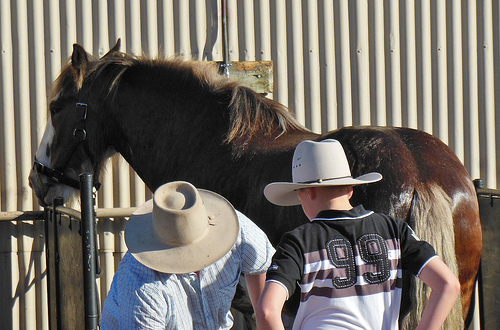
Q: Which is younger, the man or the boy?
A: The boy is younger than the man.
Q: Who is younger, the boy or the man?
A: The boy is younger than the man.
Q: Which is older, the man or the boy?
A: The man is older than the boy.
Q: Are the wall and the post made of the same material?
A: Yes, both the wall and the post are made of metal.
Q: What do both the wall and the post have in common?
A: The material, both the wall and the post are metallic.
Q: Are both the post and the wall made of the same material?
A: Yes, both the post and the wall are made of metal.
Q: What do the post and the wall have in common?
A: The material, both the post and the wall are metallic.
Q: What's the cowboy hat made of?
A: The cowboy hat is made of leather.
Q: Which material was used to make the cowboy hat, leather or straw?
A: The cowboy hat is made of leather.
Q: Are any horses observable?
A: Yes, there is a horse.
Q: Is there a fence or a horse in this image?
A: Yes, there is a horse.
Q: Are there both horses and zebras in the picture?
A: No, there is a horse but no zebras.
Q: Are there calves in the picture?
A: No, there are no calves.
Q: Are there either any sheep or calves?
A: No, there are no calves or sheep.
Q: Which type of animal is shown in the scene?
A: The animal is a horse.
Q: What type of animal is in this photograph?
A: The animal is a horse.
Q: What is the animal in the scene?
A: The animal is a horse.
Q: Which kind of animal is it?
A: The animal is a horse.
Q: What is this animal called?
A: This is a horse.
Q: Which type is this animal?
A: This is a horse.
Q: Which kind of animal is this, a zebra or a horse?
A: This is a horse.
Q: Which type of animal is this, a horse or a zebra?
A: This is a horse.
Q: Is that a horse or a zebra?
A: That is a horse.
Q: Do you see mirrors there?
A: No, there are no mirrors.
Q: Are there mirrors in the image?
A: No, there are no mirrors.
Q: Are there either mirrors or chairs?
A: No, there are no mirrors or chairs.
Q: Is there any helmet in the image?
A: No, there are no helmets.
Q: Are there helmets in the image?
A: No, there are no helmets.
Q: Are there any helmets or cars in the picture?
A: No, there are no helmets or cars.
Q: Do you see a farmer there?
A: No, there are no farmers.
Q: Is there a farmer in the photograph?
A: No, there are no farmers.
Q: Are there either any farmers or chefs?
A: No, there are no farmers or chefs.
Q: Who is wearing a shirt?
A: The man is wearing a shirt.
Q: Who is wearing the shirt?
A: The man is wearing a shirt.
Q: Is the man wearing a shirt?
A: Yes, the man is wearing a shirt.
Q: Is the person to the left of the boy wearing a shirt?
A: Yes, the man is wearing a shirt.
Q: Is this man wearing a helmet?
A: No, the man is wearing a shirt.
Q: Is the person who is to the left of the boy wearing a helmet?
A: No, the man is wearing a shirt.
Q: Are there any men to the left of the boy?
A: Yes, there is a man to the left of the boy.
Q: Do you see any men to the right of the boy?
A: No, the man is to the left of the boy.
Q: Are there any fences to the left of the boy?
A: No, there is a man to the left of the boy.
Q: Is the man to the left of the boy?
A: Yes, the man is to the left of the boy.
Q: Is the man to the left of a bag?
A: No, the man is to the left of the boy.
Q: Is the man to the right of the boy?
A: No, the man is to the left of the boy.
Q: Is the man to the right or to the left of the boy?
A: The man is to the left of the boy.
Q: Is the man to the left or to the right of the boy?
A: The man is to the left of the boy.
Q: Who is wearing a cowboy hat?
A: The man is wearing a cowboy hat.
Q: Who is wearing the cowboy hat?
A: The man is wearing a cowboy hat.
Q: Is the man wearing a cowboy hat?
A: Yes, the man is wearing a cowboy hat.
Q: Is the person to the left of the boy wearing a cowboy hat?
A: Yes, the man is wearing a cowboy hat.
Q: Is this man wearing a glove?
A: No, the man is wearing a cowboy hat.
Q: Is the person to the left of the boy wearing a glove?
A: No, the man is wearing a cowboy hat.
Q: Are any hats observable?
A: Yes, there is a hat.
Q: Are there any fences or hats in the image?
A: Yes, there is a hat.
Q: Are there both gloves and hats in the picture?
A: No, there is a hat but no gloves.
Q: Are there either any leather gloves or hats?
A: Yes, there is a leather hat.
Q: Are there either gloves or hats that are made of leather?
A: Yes, the hat is made of leather.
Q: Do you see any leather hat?
A: Yes, there is a hat that is made of leather.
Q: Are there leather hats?
A: Yes, there is a hat that is made of leather.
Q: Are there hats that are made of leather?
A: Yes, there is a hat that is made of leather.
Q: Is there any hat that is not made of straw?
A: Yes, there is a hat that is made of leather.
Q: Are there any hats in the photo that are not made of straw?
A: Yes, there is a hat that is made of leather.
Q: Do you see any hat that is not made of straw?
A: Yes, there is a hat that is made of leather.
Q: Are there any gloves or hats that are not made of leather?
A: No, there is a hat but it is made of leather.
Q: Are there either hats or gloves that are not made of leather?
A: No, there is a hat but it is made of leather.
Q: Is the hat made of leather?
A: Yes, the hat is made of leather.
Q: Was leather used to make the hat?
A: Yes, the hat is made of leather.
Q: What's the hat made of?
A: The hat is made of leather.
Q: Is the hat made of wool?
A: No, the hat is made of leather.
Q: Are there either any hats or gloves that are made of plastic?
A: No, there is a hat but it is made of leather.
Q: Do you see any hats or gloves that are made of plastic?
A: No, there is a hat but it is made of leather.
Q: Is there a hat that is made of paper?
A: No, there is a hat but it is made of leather.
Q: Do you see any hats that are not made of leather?
A: No, there is a hat but it is made of leather.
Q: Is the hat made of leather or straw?
A: The hat is made of leather.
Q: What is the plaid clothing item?
A: The clothing item is a shirt.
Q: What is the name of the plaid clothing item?
A: The clothing item is a shirt.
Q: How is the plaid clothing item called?
A: The clothing item is a shirt.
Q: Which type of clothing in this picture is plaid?
A: The clothing is a shirt.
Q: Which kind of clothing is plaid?
A: The clothing is a shirt.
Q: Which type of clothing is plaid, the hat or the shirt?
A: The shirt is plaid.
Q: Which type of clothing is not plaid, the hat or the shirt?
A: The hat is not plaid.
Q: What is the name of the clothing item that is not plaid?
A: The clothing item is a hat.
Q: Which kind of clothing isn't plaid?
A: The clothing is a hat.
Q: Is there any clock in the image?
A: No, there are no clocks.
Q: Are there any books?
A: No, there are no books.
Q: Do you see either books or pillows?
A: No, there are no books or pillows.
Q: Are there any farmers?
A: No, there are no farmers.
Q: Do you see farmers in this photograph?
A: No, there are no farmers.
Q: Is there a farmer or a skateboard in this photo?
A: No, there are no farmers or skateboards.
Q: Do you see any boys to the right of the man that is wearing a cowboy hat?
A: Yes, there is a boy to the right of the man.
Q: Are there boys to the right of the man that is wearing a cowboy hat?
A: Yes, there is a boy to the right of the man.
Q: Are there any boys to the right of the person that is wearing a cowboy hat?
A: Yes, there is a boy to the right of the man.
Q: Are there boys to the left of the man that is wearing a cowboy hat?
A: No, the boy is to the right of the man.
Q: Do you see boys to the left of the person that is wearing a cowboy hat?
A: No, the boy is to the right of the man.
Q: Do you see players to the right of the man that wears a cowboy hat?
A: No, there is a boy to the right of the man.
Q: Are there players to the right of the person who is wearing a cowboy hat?
A: No, there is a boy to the right of the man.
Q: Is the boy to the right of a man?
A: Yes, the boy is to the right of a man.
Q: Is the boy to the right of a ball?
A: No, the boy is to the right of a man.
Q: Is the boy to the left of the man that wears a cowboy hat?
A: No, the boy is to the right of the man.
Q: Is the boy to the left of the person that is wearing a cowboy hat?
A: No, the boy is to the right of the man.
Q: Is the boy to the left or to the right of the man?
A: The boy is to the right of the man.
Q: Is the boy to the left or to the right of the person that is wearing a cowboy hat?
A: The boy is to the right of the man.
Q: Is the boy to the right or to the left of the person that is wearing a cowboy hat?
A: The boy is to the right of the man.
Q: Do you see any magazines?
A: No, there are no magazines.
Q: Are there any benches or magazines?
A: No, there are no magazines or benches.